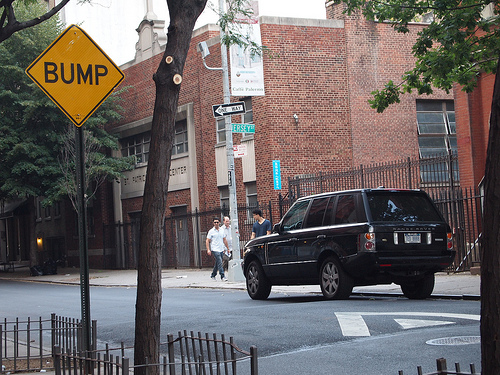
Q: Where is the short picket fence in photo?
A: Near black truck.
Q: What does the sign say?
A: Bump.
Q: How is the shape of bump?
A: Diamond.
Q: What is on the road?
A: Fence.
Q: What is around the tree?
A: Fence.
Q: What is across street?
A: Building.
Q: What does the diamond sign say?
A: Bump.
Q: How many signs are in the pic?
A: 4.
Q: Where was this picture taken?
A: Outside in the street.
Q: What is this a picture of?
A: A car parked in the street.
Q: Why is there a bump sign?
A: To warn drivers of a bump.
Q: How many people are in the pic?
A: 3.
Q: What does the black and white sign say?
A: One way.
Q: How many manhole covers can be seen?
A: 1.